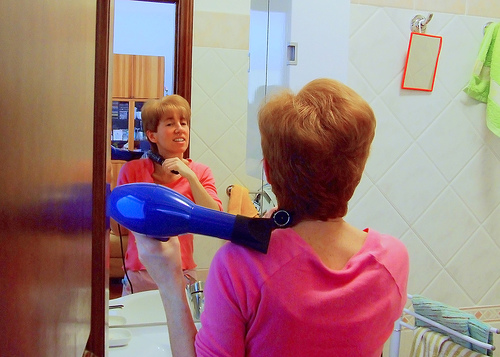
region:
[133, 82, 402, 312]
woman drying hair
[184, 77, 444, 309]
woman in a bathroom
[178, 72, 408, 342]
woman with red hair and pink shirt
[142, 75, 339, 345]
woman is standing in front of a mirror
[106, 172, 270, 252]
woman holding blue hair dryer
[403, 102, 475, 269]
white tiles on on wall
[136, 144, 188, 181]
woman holding hair brush in right hand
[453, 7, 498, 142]
lime green cloth hanging in bathroom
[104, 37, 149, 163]
cabinets in the background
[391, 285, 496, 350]
cloth items on a drying rack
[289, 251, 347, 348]
a woman in pink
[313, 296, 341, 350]
a woman in pink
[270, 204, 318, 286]
a woman in pink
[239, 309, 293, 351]
a woman in pink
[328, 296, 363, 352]
a woman in pink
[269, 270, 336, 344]
a woman in pink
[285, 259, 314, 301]
a woman in pink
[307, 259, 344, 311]
a woman in pink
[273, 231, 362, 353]
A woman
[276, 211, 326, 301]
A woman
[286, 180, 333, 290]
A woman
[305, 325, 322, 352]
A woman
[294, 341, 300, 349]
A woman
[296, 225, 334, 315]
A woman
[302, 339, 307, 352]
A woman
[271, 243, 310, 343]
A woman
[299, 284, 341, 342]
A woman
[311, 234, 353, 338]
A woman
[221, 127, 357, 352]
A woman is wearing pink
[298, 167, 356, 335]
A woman is wearing pink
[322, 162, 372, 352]
A woman is wearing pink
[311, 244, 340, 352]
A woman is wearing pink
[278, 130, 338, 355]
A woman is wearing pink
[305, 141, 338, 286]
A woman is wearing pink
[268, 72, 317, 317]
A woman is wearing pink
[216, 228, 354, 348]
A woman in pink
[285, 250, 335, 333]
A woman in pink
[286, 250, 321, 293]
A woman in pink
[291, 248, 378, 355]
A woman in pink